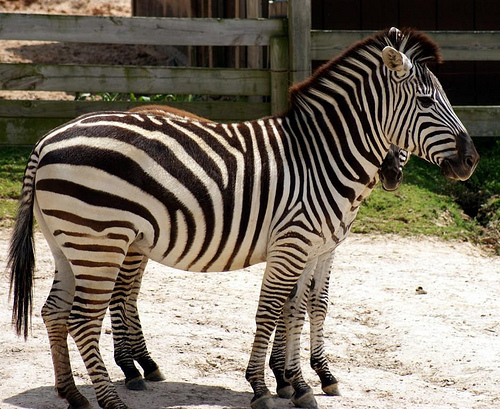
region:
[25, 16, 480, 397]
two zebras with one behind the other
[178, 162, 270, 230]
black and white stripes of zebra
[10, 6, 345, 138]
wooden fence along back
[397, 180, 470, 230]
green grass near fence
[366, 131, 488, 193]
nose of both zebras visible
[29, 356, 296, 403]
shadow cast on ground by zebra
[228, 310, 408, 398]
zebras standing in dirt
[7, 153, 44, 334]
long tail of zebra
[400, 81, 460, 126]
black eye of zebra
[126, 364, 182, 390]
hooves on zebra feet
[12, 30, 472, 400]
two zebras standing next to each other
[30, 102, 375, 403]
eight legs under zebra's belly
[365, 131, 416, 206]
a young zebra's open mouth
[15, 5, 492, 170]
wooden fence behind zebras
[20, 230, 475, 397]
dry soil with some grass in back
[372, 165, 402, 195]
lower row of curved teeth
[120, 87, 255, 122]
curve of brown mane behind black and white zebra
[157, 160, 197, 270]
one black stripe dividing into two stripes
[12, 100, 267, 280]
curves of back, rump and belly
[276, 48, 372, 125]
slight curve where neck becomes a mane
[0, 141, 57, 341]
the tail of a zebra.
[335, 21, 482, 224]
the head of a zebra.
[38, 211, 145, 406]
the right hind leg of a zebra.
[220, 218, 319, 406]
the right front leg of a zebra.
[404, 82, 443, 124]
the right eye of a zebra.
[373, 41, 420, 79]
the right ear of a zebra.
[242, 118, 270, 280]
a black stripe on a zebra.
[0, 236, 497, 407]
a dirt road.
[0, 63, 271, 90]
a board on a wooden fence.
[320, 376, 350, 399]
a zebra hoof.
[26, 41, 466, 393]
two zebras in the photo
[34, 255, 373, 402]
8 legs in the photo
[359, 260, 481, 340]
dirt that zebras are stnading on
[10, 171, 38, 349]
the tail of the zebra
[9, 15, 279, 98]
the fence of the zoo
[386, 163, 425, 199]
the nose of the second zebra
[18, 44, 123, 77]
dirt outside the fence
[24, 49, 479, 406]
zebra friends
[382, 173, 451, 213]
grass near the zebras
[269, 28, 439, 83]
hair of the first zebra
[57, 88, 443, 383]
the zebra is striped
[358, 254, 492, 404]
the sand is white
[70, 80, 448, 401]
the zebra is in sand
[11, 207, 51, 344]
the hair is black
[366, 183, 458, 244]
the grass is green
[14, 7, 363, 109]
the fence is made of wood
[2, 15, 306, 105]
the fence is gray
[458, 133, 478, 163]
the nose is black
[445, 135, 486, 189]
the mouth is black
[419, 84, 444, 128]
the eyes are black